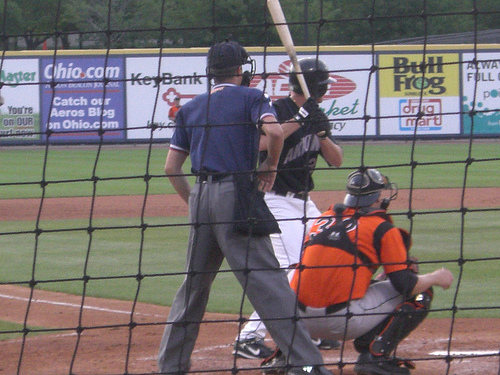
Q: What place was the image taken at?
A: It was taken at the field.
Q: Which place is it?
A: It is a field.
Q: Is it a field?
A: Yes, it is a field.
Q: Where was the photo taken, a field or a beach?
A: It was taken at a field.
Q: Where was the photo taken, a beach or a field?
A: It was taken at a field.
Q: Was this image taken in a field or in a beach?
A: It was taken at a field.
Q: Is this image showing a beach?
A: No, the picture is showing a field.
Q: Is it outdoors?
A: Yes, it is outdoors.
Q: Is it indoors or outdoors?
A: It is outdoors.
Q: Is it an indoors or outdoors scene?
A: It is outdoors.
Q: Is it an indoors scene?
A: No, it is outdoors.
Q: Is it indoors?
A: No, it is outdoors.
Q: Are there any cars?
A: No, there are no cars.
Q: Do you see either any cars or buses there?
A: No, there are no cars or buses.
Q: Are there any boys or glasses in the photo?
A: No, there are no boys or glasses.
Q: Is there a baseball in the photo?
A: Yes, there is a baseball.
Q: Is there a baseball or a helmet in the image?
A: Yes, there is a baseball.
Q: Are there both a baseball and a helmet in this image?
A: Yes, there are both a baseball and a helmet.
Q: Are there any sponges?
A: No, there are no sponges.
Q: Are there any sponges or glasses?
A: No, there are no sponges or glasses.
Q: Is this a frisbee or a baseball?
A: This is a baseball.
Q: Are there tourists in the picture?
A: No, there are no tourists.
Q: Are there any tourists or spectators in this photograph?
A: No, there are no tourists or spectators.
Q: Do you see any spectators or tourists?
A: No, there are no tourists or spectators.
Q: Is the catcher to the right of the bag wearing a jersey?
A: Yes, the catcher is wearing a jersey.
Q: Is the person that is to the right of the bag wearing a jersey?
A: Yes, the catcher is wearing a jersey.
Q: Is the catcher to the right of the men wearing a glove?
A: No, the catcher is wearing a jersey.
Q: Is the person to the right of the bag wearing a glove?
A: No, the catcher is wearing a jersey.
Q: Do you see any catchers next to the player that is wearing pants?
A: Yes, there is a catcher next to the player.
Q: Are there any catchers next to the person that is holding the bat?
A: Yes, there is a catcher next to the player.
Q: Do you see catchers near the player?
A: Yes, there is a catcher near the player.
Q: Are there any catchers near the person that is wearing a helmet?
A: Yes, there is a catcher near the player.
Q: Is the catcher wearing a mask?
A: Yes, the catcher is wearing a mask.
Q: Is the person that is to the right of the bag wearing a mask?
A: Yes, the catcher is wearing a mask.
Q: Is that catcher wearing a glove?
A: No, the catcher is wearing a mask.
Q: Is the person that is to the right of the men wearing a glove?
A: No, the catcher is wearing a mask.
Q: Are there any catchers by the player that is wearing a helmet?
A: Yes, there is a catcher by the player.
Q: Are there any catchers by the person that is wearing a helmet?
A: Yes, there is a catcher by the player.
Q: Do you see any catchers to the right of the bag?
A: Yes, there is a catcher to the right of the bag.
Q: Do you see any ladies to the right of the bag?
A: No, there is a catcher to the right of the bag.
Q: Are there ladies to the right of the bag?
A: No, there is a catcher to the right of the bag.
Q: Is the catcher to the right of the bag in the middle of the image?
A: Yes, the catcher is to the right of the bag.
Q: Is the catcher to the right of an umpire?
A: No, the catcher is to the right of the bag.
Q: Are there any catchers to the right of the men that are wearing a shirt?
A: Yes, there is a catcher to the right of the men.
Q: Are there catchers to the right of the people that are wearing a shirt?
A: Yes, there is a catcher to the right of the men.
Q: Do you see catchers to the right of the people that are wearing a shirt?
A: Yes, there is a catcher to the right of the men.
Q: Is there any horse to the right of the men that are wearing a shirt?
A: No, there is a catcher to the right of the men.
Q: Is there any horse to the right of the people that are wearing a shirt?
A: No, there is a catcher to the right of the men.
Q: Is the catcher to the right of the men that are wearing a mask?
A: Yes, the catcher is to the right of the men.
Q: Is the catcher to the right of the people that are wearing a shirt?
A: Yes, the catcher is to the right of the men.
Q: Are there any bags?
A: Yes, there is a bag.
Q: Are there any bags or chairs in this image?
A: Yes, there is a bag.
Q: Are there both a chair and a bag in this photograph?
A: No, there is a bag but no chairs.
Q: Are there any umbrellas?
A: No, there are no umbrellas.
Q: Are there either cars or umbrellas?
A: No, there are no umbrellas or cars.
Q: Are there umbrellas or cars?
A: No, there are no umbrellas or cars.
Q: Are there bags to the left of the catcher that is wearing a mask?
A: Yes, there is a bag to the left of the catcher.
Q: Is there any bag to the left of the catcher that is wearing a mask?
A: Yes, there is a bag to the left of the catcher.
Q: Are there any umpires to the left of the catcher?
A: No, there is a bag to the left of the catcher.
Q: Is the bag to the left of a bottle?
A: No, the bag is to the left of the catcher.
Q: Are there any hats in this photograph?
A: Yes, there is a hat.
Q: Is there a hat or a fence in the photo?
A: Yes, there is a hat.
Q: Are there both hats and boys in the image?
A: No, there is a hat but no boys.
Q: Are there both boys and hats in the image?
A: No, there is a hat but no boys.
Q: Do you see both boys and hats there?
A: No, there is a hat but no boys.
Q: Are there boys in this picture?
A: No, there are no boys.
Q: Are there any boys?
A: No, there are no boys.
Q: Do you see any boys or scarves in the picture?
A: No, there are no boys or scarves.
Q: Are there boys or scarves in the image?
A: No, there are no boys or scarves.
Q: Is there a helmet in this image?
A: Yes, there is a helmet.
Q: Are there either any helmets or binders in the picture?
A: Yes, there is a helmet.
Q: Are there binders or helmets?
A: Yes, there is a helmet.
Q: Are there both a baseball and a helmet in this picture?
A: Yes, there are both a helmet and a baseball.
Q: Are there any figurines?
A: No, there are no figurines.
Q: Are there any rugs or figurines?
A: No, there are no figurines or rugs.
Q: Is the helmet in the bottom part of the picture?
A: No, the helmet is in the top of the image.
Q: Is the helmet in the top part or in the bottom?
A: The helmet is in the top of the image.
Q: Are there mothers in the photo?
A: No, there are no mothers.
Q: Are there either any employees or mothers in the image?
A: No, there are no mothers or employees.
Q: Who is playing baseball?
A: The men are playing baseball.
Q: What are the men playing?
A: The men are playing baseball.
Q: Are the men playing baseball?
A: Yes, the men are playing baseball.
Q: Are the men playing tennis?
A: No, the men are playing baseball.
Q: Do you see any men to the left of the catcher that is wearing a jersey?
A: Yes, there are men to the left of the catcher.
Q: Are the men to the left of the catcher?
A: Yes, the men are to the left of the catcher.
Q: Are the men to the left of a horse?
A: No, the men are to the left of the catcher.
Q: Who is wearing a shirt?
A: The men are wearing a shirt.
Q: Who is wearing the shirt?
A: The men are wearing a shirt.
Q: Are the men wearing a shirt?
A: Yes, the men are wearing a shirt.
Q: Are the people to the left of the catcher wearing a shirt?
A: Yes, the men are wearing a shirt.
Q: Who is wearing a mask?
A: The men are wearing a mask.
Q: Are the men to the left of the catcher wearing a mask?
A: Yes, the men are wearing a mask.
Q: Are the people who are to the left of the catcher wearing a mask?
A: Yes, the men are wearing a mask.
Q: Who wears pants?
A: The men wear pants.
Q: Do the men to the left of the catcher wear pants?
A: Yes, the men wear pants.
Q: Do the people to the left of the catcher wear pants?
A: Yes, the men wear pants.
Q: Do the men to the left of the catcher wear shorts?
A: No, the men wear pants.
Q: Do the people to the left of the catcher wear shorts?
A: No, the men wear pants.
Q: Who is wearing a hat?
A: The men are wearing a hat.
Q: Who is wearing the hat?
A: The men are wearing a hat.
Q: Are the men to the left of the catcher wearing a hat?
A: Yes, the men are wearing a hat.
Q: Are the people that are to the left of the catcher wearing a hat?
A: Yes, the men are wearing a hat.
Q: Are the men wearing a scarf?
A: No, the men are wearing a hat.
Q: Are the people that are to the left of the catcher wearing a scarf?
A: No, the men are wearing a hat.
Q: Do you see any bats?
A: Yes, there is a bat.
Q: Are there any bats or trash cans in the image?
A: Yes, there is a bat.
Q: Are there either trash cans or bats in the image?
A: Yes, there is a bat.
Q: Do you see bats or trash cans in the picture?
A: Yes, there is a bat.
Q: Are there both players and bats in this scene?
A: Yes, there are both a bat and a player.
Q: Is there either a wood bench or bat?
A: Yes, there is a wood bat.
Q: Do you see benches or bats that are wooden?
A: Yes, the bat is wooden.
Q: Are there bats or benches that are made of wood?
A: Yes, the bat is made of wood.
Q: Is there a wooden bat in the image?
A: Yes, there is a wood bat.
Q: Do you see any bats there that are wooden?
A: Yes, there is a bat that is wooden.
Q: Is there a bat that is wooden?
A: Yes, there is a bat that is wooden.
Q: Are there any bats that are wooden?
A: Yes, there is a bat that is wooden.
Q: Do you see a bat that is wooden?
A: Yes, there is a bat that is wooden.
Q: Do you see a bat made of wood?
A: Yes, there is a bat that is made of wood.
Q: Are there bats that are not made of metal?
A: Yes, there is a bat that is made of wood.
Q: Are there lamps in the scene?
A: No, there are no lamps.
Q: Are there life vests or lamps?
A: No, there are no lamps or life vests.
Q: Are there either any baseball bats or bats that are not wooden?
A: No, there is a bat but it is wooden.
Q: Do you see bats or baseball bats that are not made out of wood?
A: No, there is a bat but it is made of wood.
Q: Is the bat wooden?
A: Yes, the bat is wooden.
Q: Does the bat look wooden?
A: Yes, the bat is wooden.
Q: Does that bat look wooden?
A: Yes, the bat is wooden.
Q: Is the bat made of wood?
A: Yes, the bat is made of wood.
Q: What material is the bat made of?
A: The bat is made of wood.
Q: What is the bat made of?
A: The bat is made of wood.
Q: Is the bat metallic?
A: No, the bat is wooden.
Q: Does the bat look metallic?
A: No, the bat is wooden.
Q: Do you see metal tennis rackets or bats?
A: No, there is a bat but it is wooden.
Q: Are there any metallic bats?
A: No, there is a bat but it is wooden.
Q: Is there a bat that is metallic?
A: No, there is a bat but it is wooden.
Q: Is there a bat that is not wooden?
A: No, there is a bat but it is wooden.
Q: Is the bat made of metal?
A: No, the bat is made of wood.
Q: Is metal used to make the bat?
A: No, the bat is made of wood.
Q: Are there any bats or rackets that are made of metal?
A: No, there is a bat but it is made of wood.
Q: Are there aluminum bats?
A: No, there is a bat but it is made of wood.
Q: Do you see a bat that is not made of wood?
A: No, there is a bat but it is made of wood.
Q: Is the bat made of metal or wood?
A: The bat is made of wood.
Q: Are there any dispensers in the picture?
A: No, there are no dispensers.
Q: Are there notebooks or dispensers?
A: No, there are no dispensers or notebooks.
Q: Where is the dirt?
A: The dirt is on the field.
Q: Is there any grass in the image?
A: Yes, there is grass.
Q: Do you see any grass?
A: Yes, there is grass.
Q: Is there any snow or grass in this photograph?
A: Yes, there is grass.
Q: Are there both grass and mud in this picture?
A: No, there is grass but no mud.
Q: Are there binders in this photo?
A: No, there are no binders.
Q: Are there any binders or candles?
A: No, there are no binders or candles.